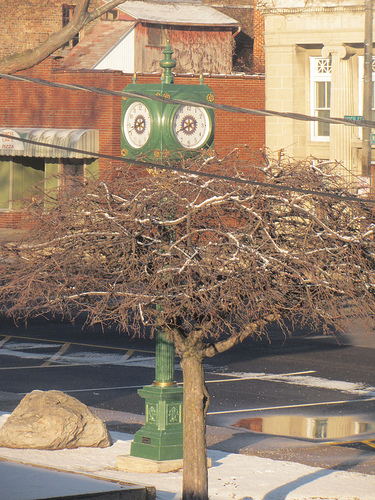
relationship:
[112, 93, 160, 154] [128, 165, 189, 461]
clock attached to pole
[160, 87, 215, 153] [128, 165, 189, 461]
clock attached to pole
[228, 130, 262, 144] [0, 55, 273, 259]
bricks on building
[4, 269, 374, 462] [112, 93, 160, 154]
street by clock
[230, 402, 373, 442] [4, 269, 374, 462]
puddle in street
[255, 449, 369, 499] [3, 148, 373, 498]
shadow of tree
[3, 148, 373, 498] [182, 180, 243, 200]
tree with snow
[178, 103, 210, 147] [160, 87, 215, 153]
face of clock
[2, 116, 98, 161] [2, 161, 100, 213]
awning over window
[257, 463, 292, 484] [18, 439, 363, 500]
snow on ground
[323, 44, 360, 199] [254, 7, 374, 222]
pillar on building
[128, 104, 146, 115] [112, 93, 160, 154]
numbers on clock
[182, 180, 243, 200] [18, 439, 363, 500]
snow covering ground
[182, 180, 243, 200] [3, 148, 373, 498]
snow covering tree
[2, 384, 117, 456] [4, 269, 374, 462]
rock beside street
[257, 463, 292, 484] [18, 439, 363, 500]
snow covering ground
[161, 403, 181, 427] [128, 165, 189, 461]
design on pole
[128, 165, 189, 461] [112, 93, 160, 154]
pole of clock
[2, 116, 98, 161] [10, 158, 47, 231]
awning over entrance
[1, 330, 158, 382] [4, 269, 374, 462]
lines on street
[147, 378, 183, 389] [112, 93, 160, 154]
ring around clock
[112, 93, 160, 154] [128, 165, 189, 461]
clock on pole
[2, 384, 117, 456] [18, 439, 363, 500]
rock on ground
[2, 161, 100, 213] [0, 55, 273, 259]
window on front of building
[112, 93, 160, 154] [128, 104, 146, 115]
clock with numbers